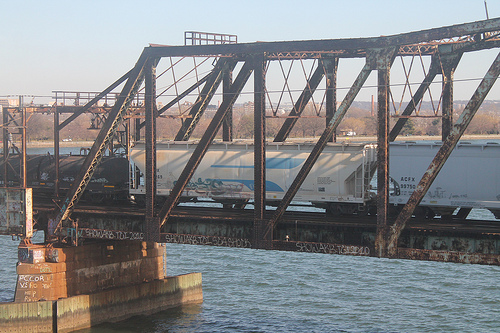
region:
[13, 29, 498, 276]
a large bridge over water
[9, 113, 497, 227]
there is a train on the bridge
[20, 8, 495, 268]
a large steel bridge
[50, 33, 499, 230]
the bridge has steel beams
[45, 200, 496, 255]
graffiti covers the bridge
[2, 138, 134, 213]
a black oil tank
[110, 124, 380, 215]
this freight car is white and blue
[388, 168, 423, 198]
black text on the side of the train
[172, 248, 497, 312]
the water is blue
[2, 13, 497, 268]
a bridge for trains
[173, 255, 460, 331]
water under the bridge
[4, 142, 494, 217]
train is on the bridge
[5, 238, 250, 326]
support block for the bridge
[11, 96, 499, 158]
trees are in the background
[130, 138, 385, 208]
the train car is white with a blue design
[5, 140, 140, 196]
the train car is black in color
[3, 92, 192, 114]
buildings are in the distance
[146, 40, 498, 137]
the bridge is made up of metal beams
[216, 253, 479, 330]
the water appears blue in color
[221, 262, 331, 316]
the water is murky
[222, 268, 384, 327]
the water is murky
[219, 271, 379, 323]
the water is murky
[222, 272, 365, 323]
the water is murky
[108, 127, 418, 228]
the container is white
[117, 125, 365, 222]
the container is white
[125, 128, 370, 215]
the container is white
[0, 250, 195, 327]
cement support of bridge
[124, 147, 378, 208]
white train with blue stripe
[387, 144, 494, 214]
white train on bridge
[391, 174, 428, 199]
black writing on car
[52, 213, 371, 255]
graffiti on train bridge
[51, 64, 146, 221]
support beam on bridge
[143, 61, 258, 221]
support beam on bridge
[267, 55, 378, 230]
support beam on bridge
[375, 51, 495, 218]
support beam on bridge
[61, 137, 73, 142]
white building on far shoreline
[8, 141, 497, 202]
train crossing bridge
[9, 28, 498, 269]
brown and rusty bridge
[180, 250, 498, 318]
water under bridge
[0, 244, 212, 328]
support for bridge in water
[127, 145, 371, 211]
white car of train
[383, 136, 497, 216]
white car of train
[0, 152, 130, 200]
short brown car of train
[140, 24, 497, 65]
upper beams of bridge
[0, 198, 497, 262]
lower structure of bridge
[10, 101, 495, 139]
trees behind bridge and water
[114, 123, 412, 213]
white train car under bridge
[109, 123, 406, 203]
white train car under bridge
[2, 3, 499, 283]
A bridge build for trains.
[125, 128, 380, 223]
A white train car with blue on it.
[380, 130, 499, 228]
A white train car with black lettering on it.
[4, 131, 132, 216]
A brown liquid train car with white on it.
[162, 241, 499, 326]
Water under the train bridge.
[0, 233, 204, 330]
A brown pillar holding the bridge up.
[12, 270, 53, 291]
White graffiti on the train pillar.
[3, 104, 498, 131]
Brown trees are in the back ground.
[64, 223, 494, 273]
White wording written on the train tracks.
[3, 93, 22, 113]
A building in the background.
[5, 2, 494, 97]
The hazy sky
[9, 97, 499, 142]
The forest of trees